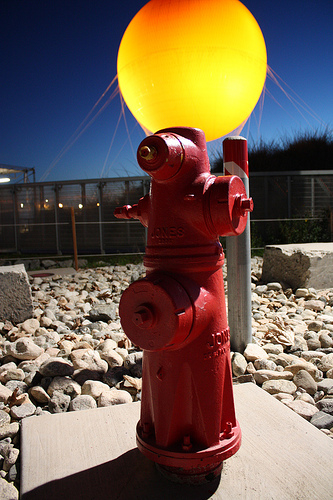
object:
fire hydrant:
[111, 125, 253, 487]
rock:
[243, 342, 267, 360]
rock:
[306, 335, 319, 350]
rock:
[292, 286, 306, 295]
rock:
[265, 281, 283, 289]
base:
[18, 384, 333, 499]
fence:
[0, 168, 332, 266]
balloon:
[116, 0, 268, 145]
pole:
[219, 133, 251, 356]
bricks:
[257, 241, 333, 293]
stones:
[80, 378, 109, 399]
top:
[136, 125, 183, 181]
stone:
[0, 260, 33, 326]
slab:
[20, 381, 333, 498]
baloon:
[114, 0, 268, 140]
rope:
[264, 65, 313, 134]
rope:
[243, 115, 254, 145]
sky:
[0, 0, 332, 185]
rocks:
[28, 384, 52, 406]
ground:
[0, 254, 332, 500]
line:
[119, 95, 141, 174]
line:
[99, 103, 125, 175]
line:
[38, 83, 119, 181]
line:
[37, 72, 120, 182]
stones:
[309, 408, 331, 428]